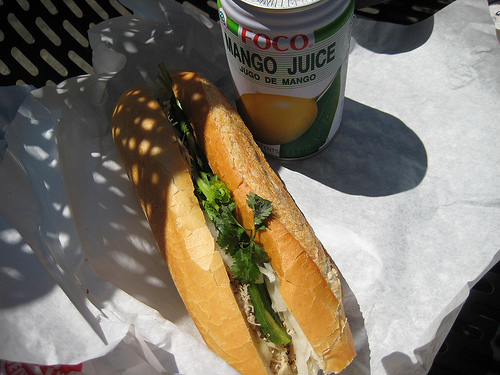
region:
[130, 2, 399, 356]
sandwich and a canned drink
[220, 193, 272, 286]
green parsley on top of sub sandwich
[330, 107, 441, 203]
shadow cast by canned drink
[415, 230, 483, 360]
white paper the food is on top of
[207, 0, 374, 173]
can of mango juice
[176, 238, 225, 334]
white bread roll cut down center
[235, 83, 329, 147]
picture of mango on canned mango juice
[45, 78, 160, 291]
sunlight making shadows on sandwich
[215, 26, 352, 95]
red and green lettering on canned drink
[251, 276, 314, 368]
cheese and meat in sandwich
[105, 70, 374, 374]
some sort of sandwich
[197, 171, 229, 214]
green bit of vegetable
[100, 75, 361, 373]
long and thin bread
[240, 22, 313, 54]
red lettering in all caps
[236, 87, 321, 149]
picture of an orange mango on the side of the can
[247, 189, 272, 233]
bit of green leaf sticking out of the folds of the bread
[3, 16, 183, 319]
shadow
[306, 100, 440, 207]
can's shadow projecting on the white napkin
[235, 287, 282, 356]
some sort of meat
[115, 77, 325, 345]
big turkey sandwich with pickles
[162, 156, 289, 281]
green vegetables in sandwich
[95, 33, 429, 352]
lunch on white paper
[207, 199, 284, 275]
parsley in turkey sandwich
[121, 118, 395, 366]
sandwich on fresh bread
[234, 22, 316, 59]
Foco juice logo on can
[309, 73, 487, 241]
shadow of juice can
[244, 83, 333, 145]
picture of mango on can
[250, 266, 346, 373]
white onions on sandwich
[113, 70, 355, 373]
tuna sandwich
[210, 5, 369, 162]
mango juice in a can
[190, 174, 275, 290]
cilantro on sandwich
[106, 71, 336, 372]
sandwich is on hoagie roll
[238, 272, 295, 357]
sandwich has green peppers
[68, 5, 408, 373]
this lunch is outside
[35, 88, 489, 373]
sandwich is on white paper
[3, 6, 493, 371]
lunch is on a park bench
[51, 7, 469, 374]
this was bought from a food truck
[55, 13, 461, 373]
It is a sunny day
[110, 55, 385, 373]
a sandwich on a hoagie roll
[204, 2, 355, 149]
a can of mango juice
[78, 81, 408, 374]
a sandwich on a piece of paper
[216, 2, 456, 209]
a can of juice casting a shadow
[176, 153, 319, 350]
cilantro on a sandwich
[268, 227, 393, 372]
a brown piece of bread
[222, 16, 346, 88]
mango juice written on a can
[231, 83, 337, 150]
a picture of a mango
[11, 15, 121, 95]
holes in a table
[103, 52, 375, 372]
a delicious looking sandwich